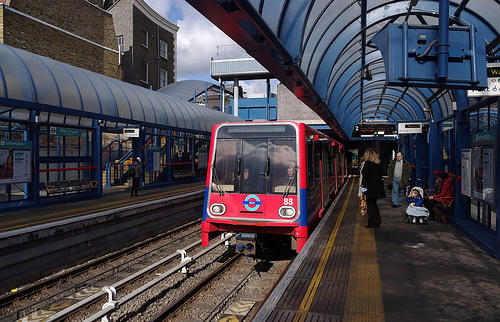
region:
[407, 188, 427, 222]
person waiting to get on the red train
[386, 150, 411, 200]
person waiting to get on the red train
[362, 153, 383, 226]
person waiting to get on the red train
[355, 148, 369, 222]
person waiting to get on the red train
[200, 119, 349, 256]
red and blue train waiting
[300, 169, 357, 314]
yellow line showing where to stand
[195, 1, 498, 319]
curved roof over platform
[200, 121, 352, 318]
parked train next to platform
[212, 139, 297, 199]
windshield with two wipers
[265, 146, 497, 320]
people on train platform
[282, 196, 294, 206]
white number on red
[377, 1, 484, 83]
back of sign on pole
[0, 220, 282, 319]
metal rails of train tracks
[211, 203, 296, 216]
two lights on front of train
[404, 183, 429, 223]
child sitting in a stroller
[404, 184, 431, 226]
child with a blanket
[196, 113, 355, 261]
red and blue train on tracks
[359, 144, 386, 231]
woman wearing black jacket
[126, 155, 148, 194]
person carrying backpack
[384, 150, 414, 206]
man in ugly brown coat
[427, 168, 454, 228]
woman sitting on a bench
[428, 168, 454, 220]
woman wearing red jacket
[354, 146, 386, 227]
woman holding purse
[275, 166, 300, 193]
person driving train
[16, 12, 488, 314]
a train station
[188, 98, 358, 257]
a train sits on the tyracks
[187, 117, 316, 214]
front train windows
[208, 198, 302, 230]
the trains headlights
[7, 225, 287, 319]
train tracks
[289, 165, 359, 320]
a yellow caution libne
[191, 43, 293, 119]
a passenger bridge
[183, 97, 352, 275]
Red and blue train on tracks.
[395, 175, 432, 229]
Child wearing blue jacket in stroller.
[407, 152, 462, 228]
Woman in red jacket sitting on bench near child.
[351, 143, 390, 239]
Woman wearing all black standing on wide yellow line.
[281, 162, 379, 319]
Three different painted lines on sidewalk.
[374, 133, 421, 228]
Man wearing jacket walking down sidewalk.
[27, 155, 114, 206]
Metal bench with bright handles.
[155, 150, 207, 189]
Red railing down side of loading tunnel.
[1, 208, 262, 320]
Two sets of train tracks.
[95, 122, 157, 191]
Blue handrails going along steps.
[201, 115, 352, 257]
red and blue train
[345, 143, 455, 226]
people waiting at train station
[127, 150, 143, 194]
girl at train station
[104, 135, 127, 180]
steps going upstairs at station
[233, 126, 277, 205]
A window on a vehicle.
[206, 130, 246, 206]
A window on a vehicle.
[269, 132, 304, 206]
A window on a vehicle.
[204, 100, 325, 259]
A train car on a track.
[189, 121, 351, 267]
a train on a track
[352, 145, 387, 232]
a person wearing black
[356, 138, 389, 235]
a blonde hair lady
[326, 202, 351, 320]
a yellow line on brick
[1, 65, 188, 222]
a blue building in back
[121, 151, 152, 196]
a person carring a purse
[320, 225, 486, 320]
shadows on the side walk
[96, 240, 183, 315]
rails by the tracks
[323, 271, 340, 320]
red bricks on the walk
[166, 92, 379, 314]
a red train on tracks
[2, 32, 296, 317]
a train station in the background